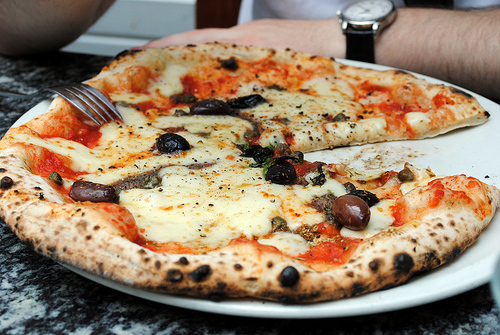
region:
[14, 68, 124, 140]
silver fork resting on plate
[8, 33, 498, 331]
pizza with one piece missing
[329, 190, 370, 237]
black olive on pizza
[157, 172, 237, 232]
melted cheese on pizza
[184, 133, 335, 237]
green spices on top of pizza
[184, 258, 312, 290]
burnt spots on crust of pizza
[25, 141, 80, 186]
tomato sauce on pizza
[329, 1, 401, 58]
watch on a wrist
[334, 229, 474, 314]
circular white plate with pizza on it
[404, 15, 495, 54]
hairy arm of a man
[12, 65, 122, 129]
A stainless steel fork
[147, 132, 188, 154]
One black olive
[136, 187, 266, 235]
Melted cheeses in this pizza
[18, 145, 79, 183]
Tomato paste on this pizza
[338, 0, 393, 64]
A watch with a black wand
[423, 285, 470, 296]
A white porcelain plate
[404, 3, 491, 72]
A hairy elbow of a man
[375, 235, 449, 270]
A toasted pan pizza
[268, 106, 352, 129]
Sprinkles of seasonings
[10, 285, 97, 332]
Dark granite counter top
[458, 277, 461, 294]
the plate is white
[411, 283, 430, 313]
the plate is white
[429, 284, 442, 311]
the plate is white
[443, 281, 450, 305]
the plate is white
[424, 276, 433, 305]
the plate is white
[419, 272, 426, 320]
the plate is white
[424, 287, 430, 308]
the plate is white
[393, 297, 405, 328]
the plate is white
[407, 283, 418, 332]
the plate is white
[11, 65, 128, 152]
There is a fork on the food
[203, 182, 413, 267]
There are olives on the pizza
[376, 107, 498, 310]
The plate is white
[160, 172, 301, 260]
There is cheese on the pizza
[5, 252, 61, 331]
The table is under the plate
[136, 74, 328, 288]
There are seasonings on the pizza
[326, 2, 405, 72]
The person has a watch on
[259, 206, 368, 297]
There is tomato sauce on the pizza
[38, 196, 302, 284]
The crust is brown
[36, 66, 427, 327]
The pizza is on a plate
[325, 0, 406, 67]
Black watch on a man's wrist.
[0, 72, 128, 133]
Silver fork sitting on the plate.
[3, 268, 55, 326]
Counter top made of marble.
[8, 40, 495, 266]
Pizza with a piece already missing.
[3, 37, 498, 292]
Pizza sitting on a white plate.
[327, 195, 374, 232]
Whole kalmata olive.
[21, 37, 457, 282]
Pizza with olives and cheese on it.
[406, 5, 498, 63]
Hair covering the man's arm.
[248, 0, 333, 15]
White shirt being worn by the man.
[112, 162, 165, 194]
Seasoning seen on top of the pizza.